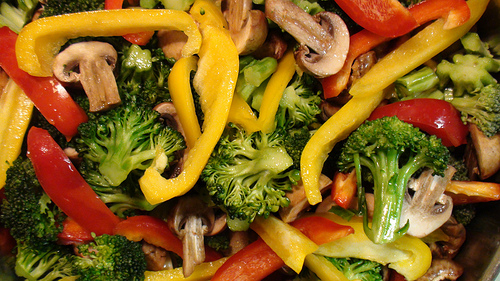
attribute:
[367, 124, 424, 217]
brocolli — green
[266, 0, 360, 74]
mushroom — brown, chopped, sliced, mixed, white, fresh, upside down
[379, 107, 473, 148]
pepper — red, chopped, sliced, yellow, fresh, chunk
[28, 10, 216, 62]
pepper — yellow, sliced, fresh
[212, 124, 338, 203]
broccoli — green, chopped, fresh, pieced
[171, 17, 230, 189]
bell pepper — long, yellow, sliced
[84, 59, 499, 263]
vegetables — sauted, steamed, chopped, sliced, chinese, stir fry, glistening, cooked, mixed, fresh, sauteed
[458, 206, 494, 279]
bowl — showing, metal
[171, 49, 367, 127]
stir fry — easy, quick